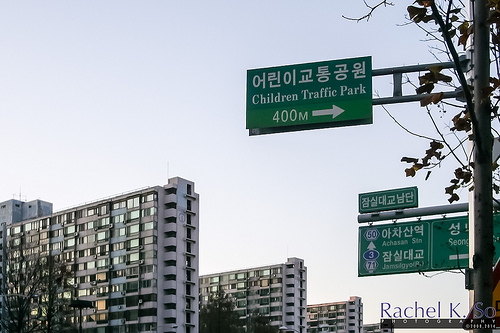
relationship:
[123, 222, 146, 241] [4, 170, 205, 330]
window on building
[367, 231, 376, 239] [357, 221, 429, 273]
numbers on sign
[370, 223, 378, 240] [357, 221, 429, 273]
numbers on sign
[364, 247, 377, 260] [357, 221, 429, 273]
numbers on sign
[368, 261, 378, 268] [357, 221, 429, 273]
numbers on sign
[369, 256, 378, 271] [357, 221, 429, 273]
numbers on sign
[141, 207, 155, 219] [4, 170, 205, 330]
window on building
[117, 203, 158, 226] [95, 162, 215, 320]
window on building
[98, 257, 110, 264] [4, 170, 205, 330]
window on building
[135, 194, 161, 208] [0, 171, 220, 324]
window on building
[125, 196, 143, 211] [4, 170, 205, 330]
window on building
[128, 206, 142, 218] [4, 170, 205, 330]
window on building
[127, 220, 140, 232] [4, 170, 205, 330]
window on building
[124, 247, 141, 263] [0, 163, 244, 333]
building window on building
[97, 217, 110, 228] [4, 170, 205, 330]
window on building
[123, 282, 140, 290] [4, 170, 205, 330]
window on building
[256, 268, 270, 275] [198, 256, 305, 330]
window on building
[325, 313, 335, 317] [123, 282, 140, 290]
window on window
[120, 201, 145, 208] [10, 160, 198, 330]
window on building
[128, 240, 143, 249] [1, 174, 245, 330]
window on building